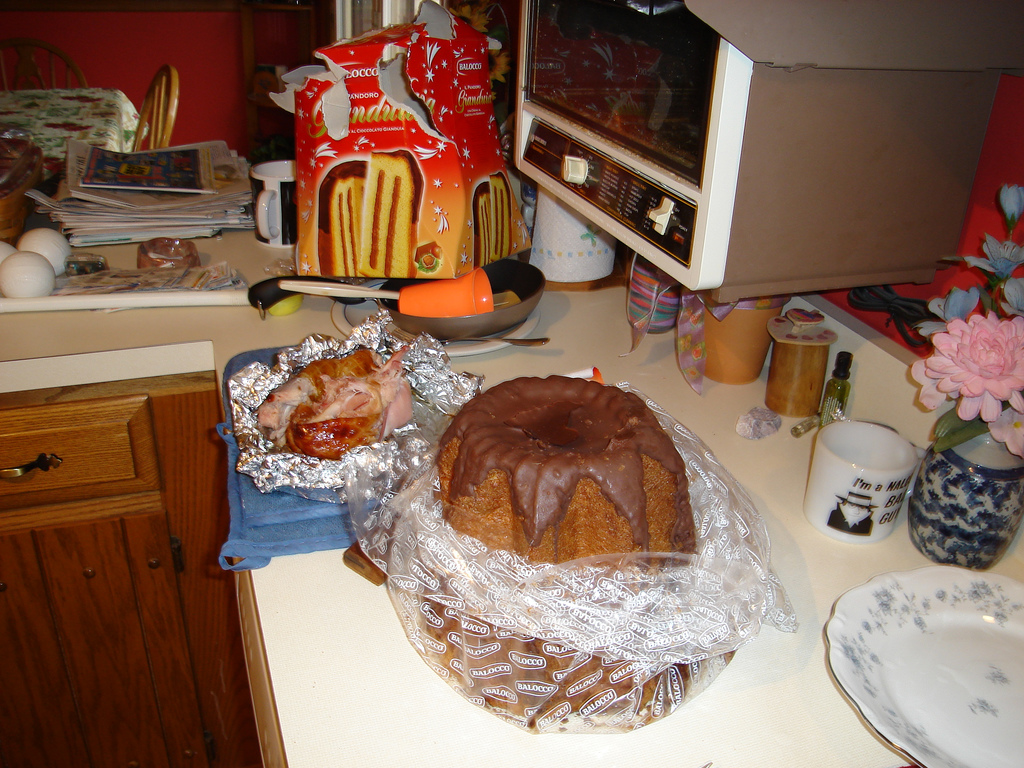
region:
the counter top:
[743, 680, 836, 758]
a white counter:
[307, 661, 388, 748]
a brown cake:
[484, 387, 661, 537]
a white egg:
[1, 254, 58, 302]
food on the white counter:
[437, 368, 695, 568]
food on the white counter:
[261, 343, 407, 460]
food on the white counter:
[20, 219, 71, 268]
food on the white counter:
[137, 232, 195, 289]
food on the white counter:
[275, 17, 547, 303]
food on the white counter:
[373, 523, 737, 727]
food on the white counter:
[289, 337, 427, 462]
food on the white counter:
[241, 346, 375, 435]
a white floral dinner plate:
[826, 564, 1019, 765]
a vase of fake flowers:
[906, 186, 1021, 575]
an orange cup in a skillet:
[393, 270, 493, 315]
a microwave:
[514, 1, 970, 299]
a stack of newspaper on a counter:
[56, 132, 257, 244]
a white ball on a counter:
[2, 252, 57, 304]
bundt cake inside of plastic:
[339, 363, 802, 738]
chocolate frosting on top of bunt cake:
[435, 372, 699, 559]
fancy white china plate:
[825, 562, 1021, 766]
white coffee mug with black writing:
[798, 417, 917, 542]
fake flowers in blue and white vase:
[904, 177, 1022, 570]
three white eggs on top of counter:
[1, 222, 74, 299]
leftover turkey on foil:
[220, 303, 484, 499]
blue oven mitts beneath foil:
[210, 345, 378, 577]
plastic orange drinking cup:
[387, 262, 498, 324]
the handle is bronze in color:
[2, 439, 69, 488]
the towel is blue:
[245, 493, 315, 535]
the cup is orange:
[420, 284, 463, 311]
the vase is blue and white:
[960, 443, 999, 541]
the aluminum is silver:
[256, 443, 315, 500]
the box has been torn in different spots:
[287, 0, 471, 144]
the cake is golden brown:
[581, 515, 616, 548]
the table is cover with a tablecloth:
[24, 95, 94, 128]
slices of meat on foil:
[222, 311, 486, 504]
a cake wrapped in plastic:
[350, 377, 803, 738]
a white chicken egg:
[2, 252, 54, 298]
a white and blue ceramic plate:
[820, 562, 1023, 765]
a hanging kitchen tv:
[507, 3, 1001, 295]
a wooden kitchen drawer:
[0, 398, 166, 500]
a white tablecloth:
[4, 81, 150, 174]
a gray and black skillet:
[236, 255, 554, 331]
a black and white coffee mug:
[235, 161, 312, 250]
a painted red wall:
[5, 0, 258, 152]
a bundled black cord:
[846, 278, 944, 354]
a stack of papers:
[55, 127, 271, 255]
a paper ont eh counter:
[111, 106, 194, 225]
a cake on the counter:
[474, 357, 708, 725]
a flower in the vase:
[935, 261, 1009, 423]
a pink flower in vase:
[945, 313, 1004, 431]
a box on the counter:
[277, 94, 528, 408]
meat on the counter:
[221, 334, 365, 461]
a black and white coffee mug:
[807, 416, 912, 546]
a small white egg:
[2, 247, 59, 298]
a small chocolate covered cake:
[433, 377, 691, 567]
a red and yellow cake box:
[256, 19, 526, 288]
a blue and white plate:
[829, 569, 1019, 765]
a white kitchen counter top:
[0, 181, 1007, 766]